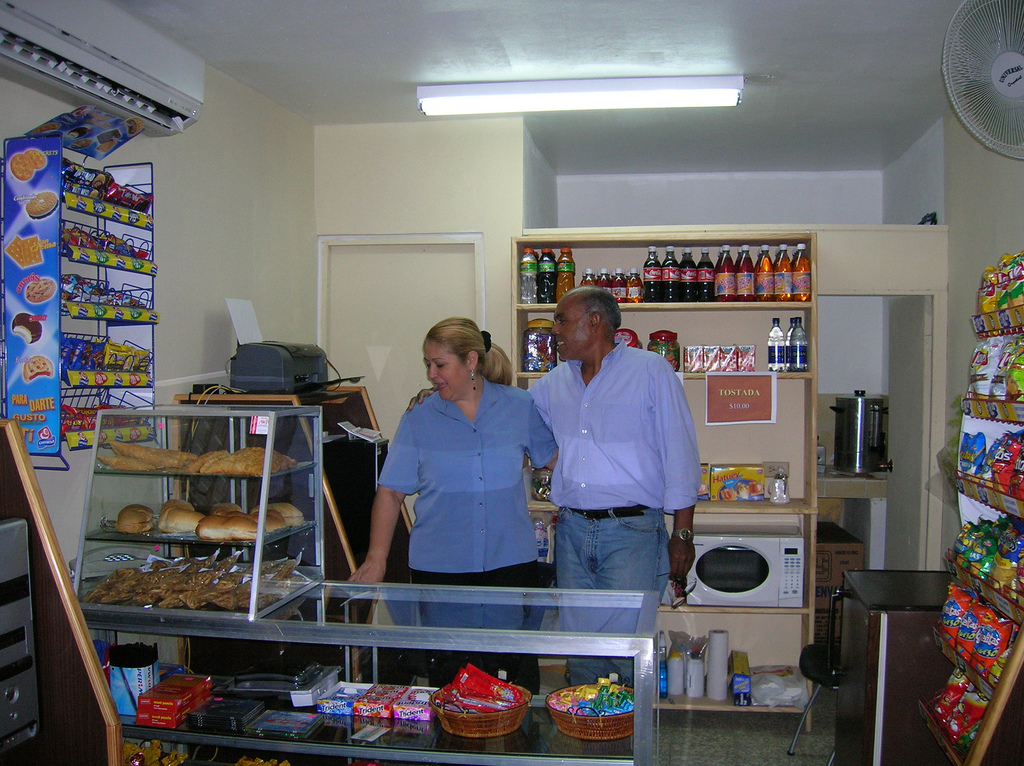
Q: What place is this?
A: It is a store.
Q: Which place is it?
A: It is a store.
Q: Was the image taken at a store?
A: Yes, it was taken in a store.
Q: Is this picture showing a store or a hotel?
A: It is showing a store.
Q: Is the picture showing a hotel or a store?
A: It is showing a store.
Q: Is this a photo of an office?
A: No, the picture is showing a store.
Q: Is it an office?
A: No, it is a store.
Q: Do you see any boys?
A: No, there are no boys.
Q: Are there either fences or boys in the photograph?
A: No, there are no boys or fences.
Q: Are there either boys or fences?
A: No, there are no boys or fences.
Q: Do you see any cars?
A: No, there are no cars.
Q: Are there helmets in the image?
A: No, there are no helmets.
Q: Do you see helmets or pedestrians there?
A: No, there are no helmets or pedestrians.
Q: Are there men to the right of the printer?
A: Yes, there is a man to the right of the printer.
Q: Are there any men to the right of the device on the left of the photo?
A: Yes, there is a man to the right of the printer.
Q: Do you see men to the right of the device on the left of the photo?
A: Yes, there is a man to the right of the printer.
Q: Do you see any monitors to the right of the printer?
A: No, there is a man to the right of the printer.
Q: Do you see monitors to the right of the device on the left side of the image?
A: No, there is a man to the right of the printer.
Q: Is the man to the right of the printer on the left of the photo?
A: Yes, the man is to the right of the printer.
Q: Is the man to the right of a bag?
A: No, the man is to the right of the printer.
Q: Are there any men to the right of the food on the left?
A: Yes, there is a man to the right of the food.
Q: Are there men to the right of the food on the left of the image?
A: Yes, there is a man to the right of the food.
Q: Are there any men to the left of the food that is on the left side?
A: No, the man is to the right of the food.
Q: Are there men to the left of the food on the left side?
A: No, the man is to the right of the food.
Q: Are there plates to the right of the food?
A: No, there is a man to the right of the food.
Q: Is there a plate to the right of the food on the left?
A: No, there is a man to the right of the food.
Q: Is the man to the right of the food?
A: Yes, the man is to the right of the food.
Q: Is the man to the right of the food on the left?
A: Yes, the man is to the right of the food.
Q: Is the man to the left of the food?
A: No, the man is to the right of the food.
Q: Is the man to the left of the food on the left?
A: No, the man is to the right of the food.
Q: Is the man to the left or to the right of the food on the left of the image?
A: The man is to the right of the food.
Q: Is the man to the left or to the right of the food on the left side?
A: The man is to the right of the food.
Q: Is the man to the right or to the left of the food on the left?
A: The man is to the right of the food.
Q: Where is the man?
A: The man is in the store.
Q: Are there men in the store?
A: Yes, there is a man in the store.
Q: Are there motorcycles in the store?
A: No, there is a man in the store.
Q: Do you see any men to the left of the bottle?
A: Yes, there is a man to the left of the bottle.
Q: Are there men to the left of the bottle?
A: Yes, there is a man to the left of the bottle.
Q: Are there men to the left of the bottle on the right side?
A: Yes, there is a man to the left of the bottle.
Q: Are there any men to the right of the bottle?
A: No, the man is to the left of the bottle.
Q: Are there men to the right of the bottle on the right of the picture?
A: No, the man is to the left of the bottle.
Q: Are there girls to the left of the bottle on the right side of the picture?
A: No, there is a man to the left of the bottle.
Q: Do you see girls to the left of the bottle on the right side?
A: No, there is a man to the left of the bottle.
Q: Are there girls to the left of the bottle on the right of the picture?
A: No, there is a man to the left of the bottle.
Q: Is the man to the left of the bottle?
A: Yes, the man is to the left of the bottle.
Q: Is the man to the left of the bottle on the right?
A: Yes, the man is to the left of the bottle.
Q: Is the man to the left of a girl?
A: No, the man is to the left of the bottle.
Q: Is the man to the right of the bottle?
A: No, the man is to the left of the bottle.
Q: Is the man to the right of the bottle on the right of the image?
A: No, the man is to the left of the bottle.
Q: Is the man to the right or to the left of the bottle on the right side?
A: The man is to the left of the bottle.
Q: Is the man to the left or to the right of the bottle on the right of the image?
A: The man is to the left of the bottle.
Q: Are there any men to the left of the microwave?
A: Yes, there is a man to the left of the microwave.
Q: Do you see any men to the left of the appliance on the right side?
A: Yes, there is a man to the left of the microwave.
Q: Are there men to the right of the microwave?
A: No, the man is to the left of the microwave.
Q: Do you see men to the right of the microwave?
A: No, the man is to the left of the microwave.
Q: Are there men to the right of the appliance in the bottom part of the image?
A: No, the man is to the left of the microwave.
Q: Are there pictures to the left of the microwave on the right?
A: No, there is a man to the left of the microwave.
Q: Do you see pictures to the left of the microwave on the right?
A: No, there is a man to the left of the microwave.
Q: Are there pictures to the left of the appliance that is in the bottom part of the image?
A: No, there is a man to the left of the microwave.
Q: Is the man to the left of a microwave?
A: Yes, the man is to the left of a microwave.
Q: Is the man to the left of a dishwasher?
A: No, the man is to the left of a microwave.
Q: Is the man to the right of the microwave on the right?
A: No, the man is to the left of the microwave.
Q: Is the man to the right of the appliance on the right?
A: No, the man is to the left of the microwave.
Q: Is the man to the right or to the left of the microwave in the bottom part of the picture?
A: The man is to the left of the microwave.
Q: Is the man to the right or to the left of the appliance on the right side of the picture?
A: The man is to the left of the microwave.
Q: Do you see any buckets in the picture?
A: No, there are no buckets.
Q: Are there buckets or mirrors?
A: No, there are no buckets or mirrors.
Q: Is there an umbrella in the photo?
A: No, there are no umbrellas.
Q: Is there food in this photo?
A: Yes, there is food.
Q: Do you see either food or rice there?
A: Yes, there is food.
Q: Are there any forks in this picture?
A: No, there are no forks.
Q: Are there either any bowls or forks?
A: No, there are no forks or bowls.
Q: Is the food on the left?
A: Yes, the food is on the left of the image.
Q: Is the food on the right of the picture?
A: No, the food is on the left of the image.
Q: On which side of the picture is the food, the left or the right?
A: The food is on the left of the image.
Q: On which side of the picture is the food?
A: The food is on the left of the image.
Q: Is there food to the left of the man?
A: Yes, there is food to the left of the man.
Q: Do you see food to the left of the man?
A: Yes, there is food to the left of the man.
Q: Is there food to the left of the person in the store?
A: Yes, there is food to the left of the man.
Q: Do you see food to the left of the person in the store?
A: Yes, there is food to the left of the man.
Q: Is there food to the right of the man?
A: No, the food is to the left of the man.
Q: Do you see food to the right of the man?
A: No, the food is to the left of the man.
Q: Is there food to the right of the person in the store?
A: No, the food is to the left of the man.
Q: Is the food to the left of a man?
A: Yes, the food is to the left of a man.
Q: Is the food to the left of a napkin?
A: No, the food is to the left of a man.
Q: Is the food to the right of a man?
A: No, the food is to the left of a man.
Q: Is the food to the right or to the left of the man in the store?
A: The food is to the left of the man.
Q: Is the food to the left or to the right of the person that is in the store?
A: The food is to the left of the man.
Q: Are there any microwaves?
A: Yes, there is a microwave.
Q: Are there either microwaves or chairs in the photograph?
A: Yes, there is a microwave.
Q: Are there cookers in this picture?
A: No, there are no cookers.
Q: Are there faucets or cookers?
A: No, there are no cookers or faucets.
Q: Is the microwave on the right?
A: Yes, the microwave is on the right of the image.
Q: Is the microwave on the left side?
A: No, the microwave is on the right of the image.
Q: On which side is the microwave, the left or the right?
A: The microwave is on the right of the image.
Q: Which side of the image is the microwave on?
A: The microwave is on the right of the image.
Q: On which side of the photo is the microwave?
A: The microwave is on the right of the image.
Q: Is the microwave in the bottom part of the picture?
A: Yes, the microwave is in the bottom of the image.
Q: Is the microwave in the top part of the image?
A: No, the microwave is in the bottom of the image.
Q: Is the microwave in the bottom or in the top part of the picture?
A: The microwave is in the bottom of the image.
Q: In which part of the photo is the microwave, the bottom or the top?
A: The microwave is in the bottom of the image.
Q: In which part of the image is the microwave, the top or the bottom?
A: The microwave is in the bottom of the image.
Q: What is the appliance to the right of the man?
A: The appliance is a microwave.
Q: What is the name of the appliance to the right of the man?
A: The appliance is a microwave.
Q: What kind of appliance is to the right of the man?
A: The appliance is a microwave.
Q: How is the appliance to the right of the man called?
A: The appliance is a microwave.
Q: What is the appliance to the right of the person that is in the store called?
A: The appliance is a microwave.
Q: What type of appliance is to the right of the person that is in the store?
A: The appliance is a microwave.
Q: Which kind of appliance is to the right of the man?
A: The appliance is a microwave.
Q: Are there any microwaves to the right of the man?
A: Yes, there is a microwave to the right of the man.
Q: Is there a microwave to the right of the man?
A: Yes, there is a microwave to the right of the man.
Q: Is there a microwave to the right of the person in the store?
A: Yes, there is a microwave to the right of the man.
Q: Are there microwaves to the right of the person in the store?
A: Yes, there is a microwave to the right of the man.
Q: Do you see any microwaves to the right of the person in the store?
A: Yes, there is a microwave to the right of the man.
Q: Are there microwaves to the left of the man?
A: No, the microwave is to the right of the man.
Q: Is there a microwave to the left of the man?
A: No, the microwave is to the right of the man.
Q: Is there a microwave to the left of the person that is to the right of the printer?
A: No, the microwave is to the right of the man.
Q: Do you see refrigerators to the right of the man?
A: No, there is a microwave to the right of the man.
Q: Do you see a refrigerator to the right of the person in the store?
A: No, there is a microwave to the right of the man.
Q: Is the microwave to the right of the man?
A: Yes, the microwave is to the right of the man.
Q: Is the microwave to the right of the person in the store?
A: Yes, the microwave is to the right of the man.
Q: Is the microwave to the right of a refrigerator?
A: No, the microwave is to the right of the man.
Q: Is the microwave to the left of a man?
A: No, the microwave is to the right of a man.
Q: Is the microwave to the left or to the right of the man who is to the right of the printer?
A: The microwave is to the right of the man.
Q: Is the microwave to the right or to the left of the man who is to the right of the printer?
A: The microwave is to the right of the man.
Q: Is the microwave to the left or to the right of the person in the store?
A: The microwave is to the right of the man.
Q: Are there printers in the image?
A: Yes, there is a printer.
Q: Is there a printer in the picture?
A: Yes, there is a printer.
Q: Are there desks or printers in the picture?
A: Yes, there is a printer.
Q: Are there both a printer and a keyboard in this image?
A: No, there is a printer but no keyboards.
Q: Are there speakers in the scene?
A: No, there are no speakers.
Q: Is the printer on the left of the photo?
A: Yes, the printer is on the left of the image.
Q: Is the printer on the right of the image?
A: No, the printer is on the left of the image.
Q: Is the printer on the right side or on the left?
A: The printer is on the left of the image.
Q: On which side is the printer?
A: The printer is on the left of the image.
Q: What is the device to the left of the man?
A: The device is a printer.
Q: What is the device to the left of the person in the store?
A: The device is a printer.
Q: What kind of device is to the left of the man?
A: The device is a printer.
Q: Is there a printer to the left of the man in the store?
A: Yes, there is a printer to the left of the man.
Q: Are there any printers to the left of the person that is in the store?
A: Yes, there is a printer to the left of the man.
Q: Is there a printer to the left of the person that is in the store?
A: Yes, there is a printer to the left of the man.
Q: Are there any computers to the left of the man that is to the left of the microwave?
A: No, there is a printer to the left of the man.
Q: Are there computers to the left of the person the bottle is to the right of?
A: No, there is a printer to the left of the man.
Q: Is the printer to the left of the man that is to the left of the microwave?
A: Yes, the printer is to the left of the man.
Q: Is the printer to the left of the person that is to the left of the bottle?
A: Yes, the printer is to the left of the man.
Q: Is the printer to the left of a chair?
A: No, the printer is to the left of the man.